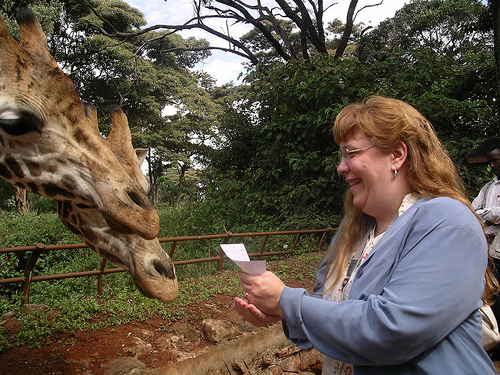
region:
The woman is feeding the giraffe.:
[14, 14, 499, 366]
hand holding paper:
[213, 239, 286, 328]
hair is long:
[320, 85, 498, 308]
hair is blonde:
[295, 84, 491, 323]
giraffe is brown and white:
[0, 4, 193, 314]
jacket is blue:
[293, 185, 496, 363]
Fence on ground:
[3, 218, 372, 293]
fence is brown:
[5, 219, 391, 289]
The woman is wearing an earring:
[380, 158, 407, 184]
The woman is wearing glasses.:
[330, 142, 377, 165]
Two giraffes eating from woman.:
[7, 0, 191, 305]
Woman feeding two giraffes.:
[229, 113, 499, 374]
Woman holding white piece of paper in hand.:
[216, 238, 298, 306]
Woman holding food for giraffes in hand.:
[231, 293, 288, 335]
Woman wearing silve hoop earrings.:
[386, 164, 407, 181]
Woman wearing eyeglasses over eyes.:
[326, 146, 389, 167]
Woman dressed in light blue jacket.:
[278, 192, 494, 374]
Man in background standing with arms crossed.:
[468, 143, 498, 267]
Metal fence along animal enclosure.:
[176, 228, 345, 271]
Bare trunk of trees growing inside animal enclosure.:
[146, 1, 402, 68]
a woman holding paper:
[220, 93, 493, 373]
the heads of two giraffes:
[2, 13, 182, 308]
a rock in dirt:
[198, 313, 240, 339]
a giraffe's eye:
[0, 111, 41, 139]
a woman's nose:
[336, 161, 350, 175]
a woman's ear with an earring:
[389, 140, 409, 182]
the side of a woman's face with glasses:
[334, 137, 407, 214]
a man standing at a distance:
[472, 148, 498, 282]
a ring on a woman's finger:
[242, 291, 251, 300]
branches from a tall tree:
[94, 2, 361, 79]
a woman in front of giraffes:
[11, 9, 492, 368]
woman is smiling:
[283, 71, 475, 239]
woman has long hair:
[311, 86, 498, 301]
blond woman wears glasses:
[273, 71, 499, 326]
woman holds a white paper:
[211, 92, 495, 370]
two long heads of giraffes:
[5, 35, 205, 322]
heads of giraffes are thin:
[2, 37, 200, 318]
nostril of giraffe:
[123, 177, 155, 219]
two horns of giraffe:
[80, 87, 142, 147]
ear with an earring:
[379, 133, 418, 191]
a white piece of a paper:
[215, 235, 272, 272]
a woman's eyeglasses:
[336, 142, 372, 159]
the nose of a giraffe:
[124, 186, 150, 213]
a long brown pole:
[0, 220, 342, 255]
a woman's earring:
[390, 167, 400, 175]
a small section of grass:
[55, 292, 105, 330]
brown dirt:
[90, 336, 122, 358]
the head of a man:
[487, 145, 499, 176]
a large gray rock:
[202, 317, 242, 339]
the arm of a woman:
[274, 200, 486, 361]